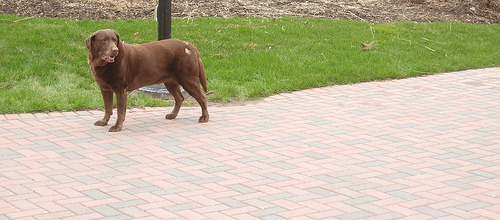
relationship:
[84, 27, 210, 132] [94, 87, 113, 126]
dog has leg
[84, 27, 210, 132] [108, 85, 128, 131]
dog has leg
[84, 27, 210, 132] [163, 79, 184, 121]
dog has leg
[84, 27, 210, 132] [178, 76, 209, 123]
dog has leg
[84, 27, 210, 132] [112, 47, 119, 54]
dog has nose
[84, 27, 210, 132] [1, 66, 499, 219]
dog on ground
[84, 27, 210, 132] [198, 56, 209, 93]
dog has tail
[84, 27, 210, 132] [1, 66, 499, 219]
dog standing on ground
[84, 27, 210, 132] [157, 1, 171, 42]
dog standing before pole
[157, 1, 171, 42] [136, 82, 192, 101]
pole has bottom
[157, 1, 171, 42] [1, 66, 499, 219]
pole beside ground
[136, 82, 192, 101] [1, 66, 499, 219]
bottom beside ground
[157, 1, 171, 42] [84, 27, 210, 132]
pole behind dog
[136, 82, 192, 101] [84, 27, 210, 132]
bottom behind dog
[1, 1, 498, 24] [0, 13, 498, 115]
grass behind grass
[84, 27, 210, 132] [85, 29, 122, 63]
dog has head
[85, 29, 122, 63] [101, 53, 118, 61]
head has mouth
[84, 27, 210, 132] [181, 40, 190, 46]
dog has spot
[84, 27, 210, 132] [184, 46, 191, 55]
dog has spot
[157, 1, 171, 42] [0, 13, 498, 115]
pole in grass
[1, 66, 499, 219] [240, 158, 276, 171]
ground made of brick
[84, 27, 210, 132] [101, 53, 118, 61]
dog has mouth